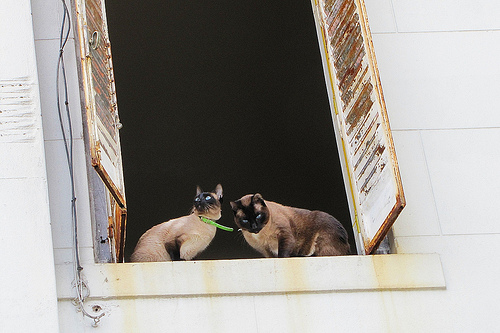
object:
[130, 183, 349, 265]
cats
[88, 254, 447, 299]
ledge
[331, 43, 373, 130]
shutter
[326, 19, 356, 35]
rust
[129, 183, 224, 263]
cat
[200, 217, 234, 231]
green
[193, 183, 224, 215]
up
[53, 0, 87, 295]
lines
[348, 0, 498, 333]
building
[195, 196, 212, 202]
eyes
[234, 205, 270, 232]
face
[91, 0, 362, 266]
window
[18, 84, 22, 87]
hole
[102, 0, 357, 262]
darkness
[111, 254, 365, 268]
edge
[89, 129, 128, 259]
part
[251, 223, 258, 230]
nose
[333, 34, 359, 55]
rusty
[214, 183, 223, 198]
ear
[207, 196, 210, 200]
blue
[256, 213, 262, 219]
eye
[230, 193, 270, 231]
head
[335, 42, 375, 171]
shutters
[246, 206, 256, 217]
black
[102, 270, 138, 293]
wall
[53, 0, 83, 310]
wire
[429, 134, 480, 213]
wall